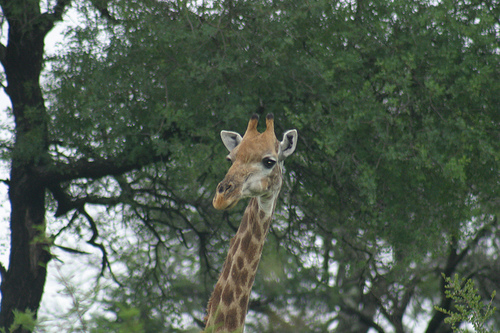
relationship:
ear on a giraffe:
[263, 114, 275, 130] [198, 109, 298, 331]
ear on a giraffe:
[245, 115, 260, 132] [198, 109, 298, 331]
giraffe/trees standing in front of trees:
[166, 44, 350, 330] [46, 0, 214, 200]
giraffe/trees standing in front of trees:
[166, 44, 350, 330] [305, 0, 499, 275]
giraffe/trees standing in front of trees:
[166, 44, 350, 330] [181, 0, 323, 95]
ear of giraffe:
[276, 122, 299, 162] [198, 109, 298, 331]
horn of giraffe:
[265, 110, 273, 133] [184, 100, 312, 331]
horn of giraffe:
[242, 105, 258, 134] [184, 100, 312, 331]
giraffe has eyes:
[153, 117, 345, 303] [209, 143, 246, 166]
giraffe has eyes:
[153, 117, 345, 303] [260, 145, 317, 187]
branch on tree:
[40, 122, 182, 202] [0, 0, 185, 332]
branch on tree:
[46, 177, 207, 285] [2, 2, 376, 320]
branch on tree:
[40, 1, 72, 36] [0, 0, 215, 331]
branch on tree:
[50, 32, 334, 177] [2, 2, 376, 320]